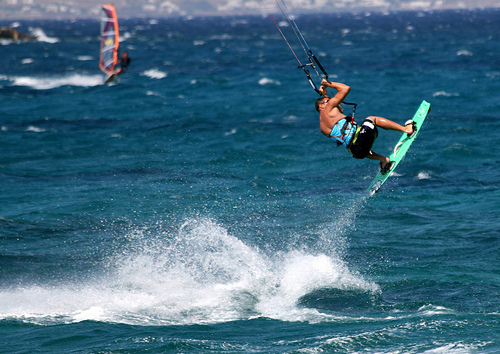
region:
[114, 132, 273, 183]
the water is blue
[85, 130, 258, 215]
the water is blue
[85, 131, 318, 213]
the water is blue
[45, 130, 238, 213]
the water is blue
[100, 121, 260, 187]
the water is blue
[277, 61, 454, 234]
the man is surfing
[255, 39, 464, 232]
the man is surfing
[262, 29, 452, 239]
the man is surfing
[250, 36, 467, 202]
the man is surfing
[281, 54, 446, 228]
the man is surfing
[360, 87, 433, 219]
green water ski board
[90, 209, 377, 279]
white water splash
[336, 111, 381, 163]
black shorts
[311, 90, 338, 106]
pair of glasses on man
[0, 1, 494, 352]
blue-green body of water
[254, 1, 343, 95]
cords in air with black handles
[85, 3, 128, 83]
orange water ski sail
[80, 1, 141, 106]
person standing on ski board with sail in ocean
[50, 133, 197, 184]
dark line ripples in water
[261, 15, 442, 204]
guy in air with surf board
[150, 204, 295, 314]
splashing water in air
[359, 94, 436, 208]
teal surf board with feet in it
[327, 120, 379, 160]
men's swim suit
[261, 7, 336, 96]
handles and wires with hands holding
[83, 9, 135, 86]
guy sea gliding on water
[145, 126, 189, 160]
water ripples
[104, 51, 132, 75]
men's swimming suit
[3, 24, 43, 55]
small rock in water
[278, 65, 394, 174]
this is a person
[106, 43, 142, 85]
this is a person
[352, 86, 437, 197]
this is a surf board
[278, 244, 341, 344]
this is a wave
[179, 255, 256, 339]
this is a wave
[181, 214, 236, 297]
this is a wave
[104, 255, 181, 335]
this is a wave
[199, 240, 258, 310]
this is a wave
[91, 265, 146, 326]
this is a wave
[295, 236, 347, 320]
this is a wave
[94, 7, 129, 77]
a person wind surfing in the water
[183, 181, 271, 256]
splashes from the water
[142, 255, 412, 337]
waves in the water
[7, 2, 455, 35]
a mountain behind the water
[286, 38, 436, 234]
a person on a surf board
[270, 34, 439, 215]
a man wind surfing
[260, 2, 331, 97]
the strings of the kite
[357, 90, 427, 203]
the blue surf board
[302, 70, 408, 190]
a man jumping out of the water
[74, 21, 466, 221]
people in the water